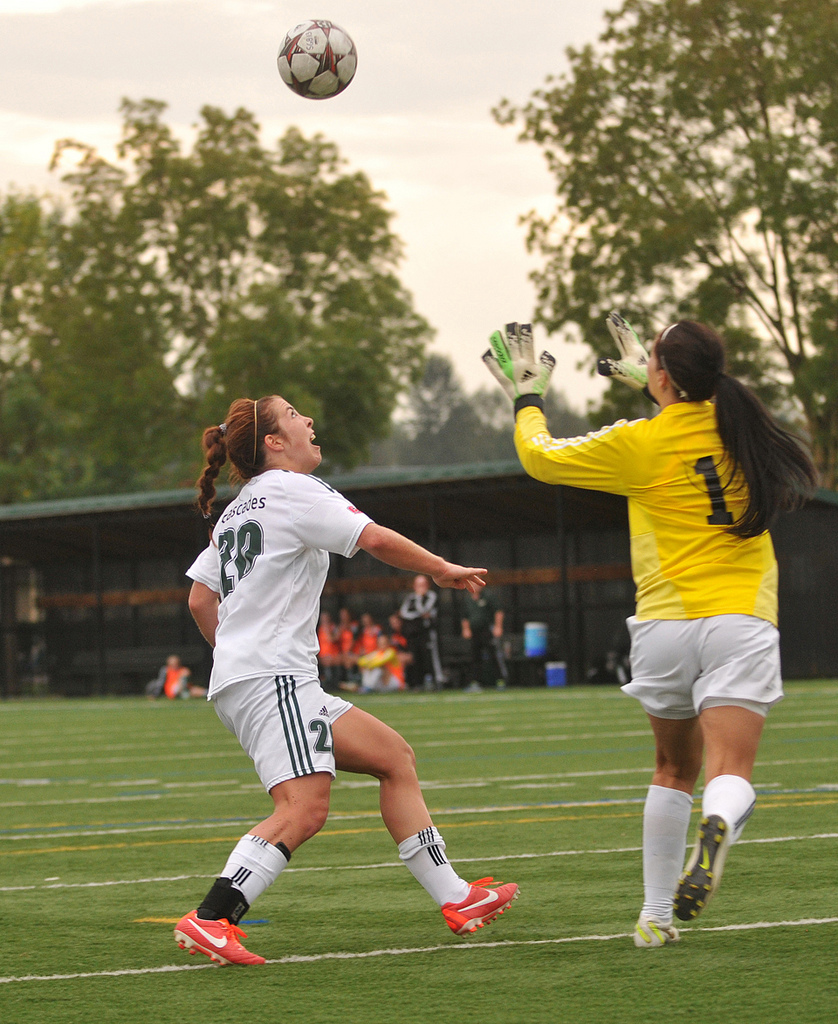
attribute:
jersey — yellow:
[509, 394, 778, 653]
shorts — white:
[218, 669, 352, 790]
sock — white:
[696, 771, 753, 848]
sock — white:
[631, 777, 704, 932]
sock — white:
[398, 818, 466, 903]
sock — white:
[227, 827, 286, 912]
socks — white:
[705, 772, 764, 839]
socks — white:
[635, 780, 700, 923]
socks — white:
[395, 821, 471, 907]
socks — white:
[218, 830, 281, 903]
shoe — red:
[436, 873, 527, 936]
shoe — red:
[177, 908, 272, 973]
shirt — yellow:
[509, 399, 795, 627]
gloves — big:
[480, 315, 563, 406]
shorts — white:
[623, 617, 787, 717]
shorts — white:
[212, 676, 361, 788]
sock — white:
[692, 775, 759, 826]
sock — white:
[635, 784, 694, 925]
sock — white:
[393, 825, 472, 908]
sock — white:
[209, 827, 286, 909]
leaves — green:
[491, 0, 836, 495]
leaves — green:
[1, 93, 442, 504]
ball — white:
[277, 18, 360, 100]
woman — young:
[114, 330, 481, 960]